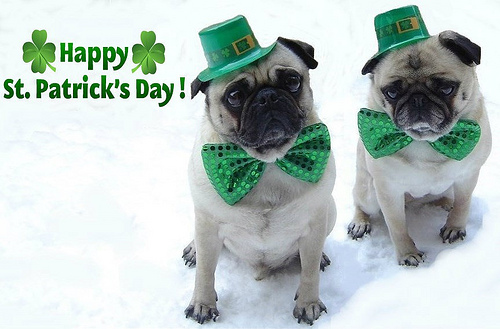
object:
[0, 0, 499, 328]
advertisement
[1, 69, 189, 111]
st. patrick's day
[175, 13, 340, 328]
dog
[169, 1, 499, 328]
two dogs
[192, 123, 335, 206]
bowties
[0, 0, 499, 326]
background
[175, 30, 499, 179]
uninterested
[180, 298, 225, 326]
paws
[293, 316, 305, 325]
nails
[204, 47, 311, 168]
pug faces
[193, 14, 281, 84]
hats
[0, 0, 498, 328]
snow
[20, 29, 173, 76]
two four leaf clover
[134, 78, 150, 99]
writing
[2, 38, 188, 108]
happy st. patricks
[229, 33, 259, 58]
gold buckles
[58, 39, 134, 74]
happy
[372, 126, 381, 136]
sequins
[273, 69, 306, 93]
eye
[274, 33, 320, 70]
ear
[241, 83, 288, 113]
snout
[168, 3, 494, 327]
eachother